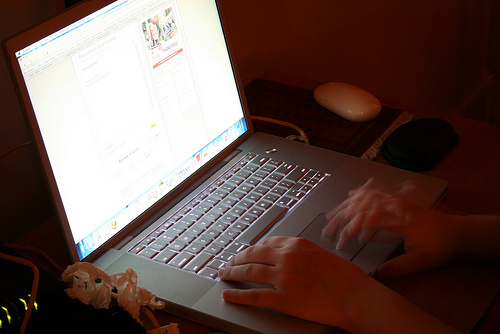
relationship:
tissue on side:
[48, 246, 137, 315] [60, 258, 156, 332]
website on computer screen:
[31, 1, 217, 270] [38, 26, 235, 193]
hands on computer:
[218, 167, 450, 325] [2, 2, 456, 332]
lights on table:
[1, 290, 45, 331] [12, 251, 196, 332]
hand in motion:
[321, 183, 458, 289] [341, 170, 443, 251]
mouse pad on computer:
[286, 205, 391, 280] [0, 0, 452, 333]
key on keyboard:
[254, 176, 263, 186] [193, 152, 312, 224]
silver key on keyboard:
[174, 232, 193, 244] [129, 147, 329, 281]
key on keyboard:
[182, 247, 213, 272] [88, 131, 333, 283]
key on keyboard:
[166, 250, 195, 269] [88, 131, 333, 283]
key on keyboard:
[211, 233, 236, 246] [88, 131, 333, 283]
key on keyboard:
[167, 240, 190, 250] [88, 131, 333, 283]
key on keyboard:
[136, 245, 162, 258] [129, 147, 329, 281]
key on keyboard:
[155, 246, 179, 263] [129, 147, 329, 281]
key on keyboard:
[182, 247, 213, 272] [129, 147, 329, 281]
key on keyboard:
[184, 242, 204, 254] [129, 147, 329, 281]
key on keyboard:
[166, 250, 195, 269] [129, 147, 329, 281]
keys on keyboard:
[264, 158, 281, 165] [129, 147, 329, 281]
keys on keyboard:
[281, 162, 310, 184] [129, 147, 329, 281]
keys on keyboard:
[273, 193, 290, 208] [129, 147, 329, 281]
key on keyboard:
[202, 241, 225, 254] [129, 147, 329, 281]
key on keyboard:
[136, 245, 162, 258] [90, 132, 448, 330]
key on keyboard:
[166, 250, 195, 269] [90, 132, 448, 330]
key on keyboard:
[182, 247, 213, 272] [90, 132, 448, 330]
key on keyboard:
[259, 177, 279, 192] [90, 132, 448, 330]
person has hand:
[216, 179, 498, 331] [218, 230, 368, 327]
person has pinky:
[216, 179, 498, 331] [212, 284, 283, 312]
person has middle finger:
[216, 179, 498, 331] [206, 246, 285, 264]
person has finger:
[216, 179, 498, 331] [256, 235, 298, 249]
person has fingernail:
[216, 179, 498, 331] [221, 289, 231, 299]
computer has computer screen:
[2, 2, 456, 332] [14, 0, 247, 261]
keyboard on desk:
[132, 160, 324, 292] [64, 85, 442, 331]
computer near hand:
[2, 2, 456, 332] [210, 232, 370, 332]